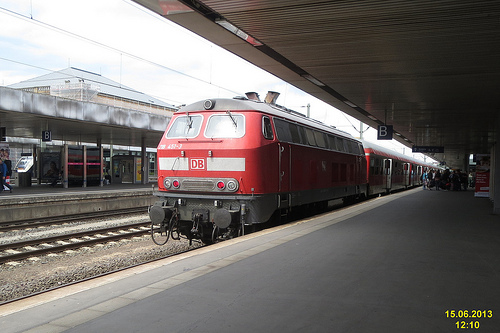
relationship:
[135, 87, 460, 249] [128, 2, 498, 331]
train at station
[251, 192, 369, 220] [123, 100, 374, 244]
edge of train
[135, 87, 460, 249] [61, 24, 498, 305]
train at station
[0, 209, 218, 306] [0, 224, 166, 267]
ground between rails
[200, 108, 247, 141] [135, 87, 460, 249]
windshield on train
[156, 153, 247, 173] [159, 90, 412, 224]
line on train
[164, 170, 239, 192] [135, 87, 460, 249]
headlight on train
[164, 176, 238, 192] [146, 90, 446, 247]
headlight on train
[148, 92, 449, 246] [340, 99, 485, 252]
train stopped in terminal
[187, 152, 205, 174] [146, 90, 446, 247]
letter on train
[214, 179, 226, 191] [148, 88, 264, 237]
red light on front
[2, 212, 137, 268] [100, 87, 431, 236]
tracks between train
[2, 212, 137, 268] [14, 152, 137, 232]
tracks between platform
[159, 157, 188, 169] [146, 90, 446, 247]
patch on train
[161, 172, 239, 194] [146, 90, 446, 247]
headlights on train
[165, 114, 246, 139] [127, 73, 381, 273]
windshield on train engine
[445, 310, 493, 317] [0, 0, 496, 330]
date is in photograph